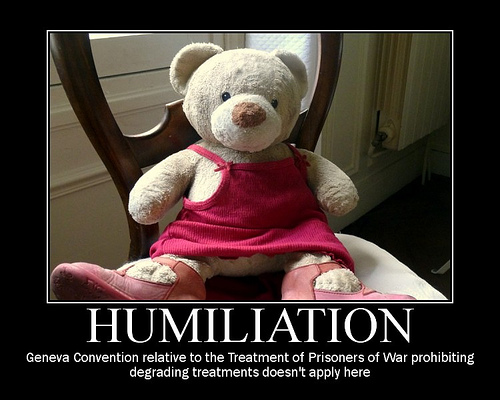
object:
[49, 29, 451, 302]
chair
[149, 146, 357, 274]
dress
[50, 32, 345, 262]
chair back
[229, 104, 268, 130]
nose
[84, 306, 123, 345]
letters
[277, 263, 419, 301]
shoe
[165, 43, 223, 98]
ear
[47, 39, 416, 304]
bear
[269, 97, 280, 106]
eyes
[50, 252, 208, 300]
shoes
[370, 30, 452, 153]
radiator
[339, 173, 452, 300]
floor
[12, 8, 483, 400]
poster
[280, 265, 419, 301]
foot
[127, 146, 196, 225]
arm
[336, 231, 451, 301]
seat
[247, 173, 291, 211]
cloth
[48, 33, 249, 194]
door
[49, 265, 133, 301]
sole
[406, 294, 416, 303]
tip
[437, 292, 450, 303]
edge